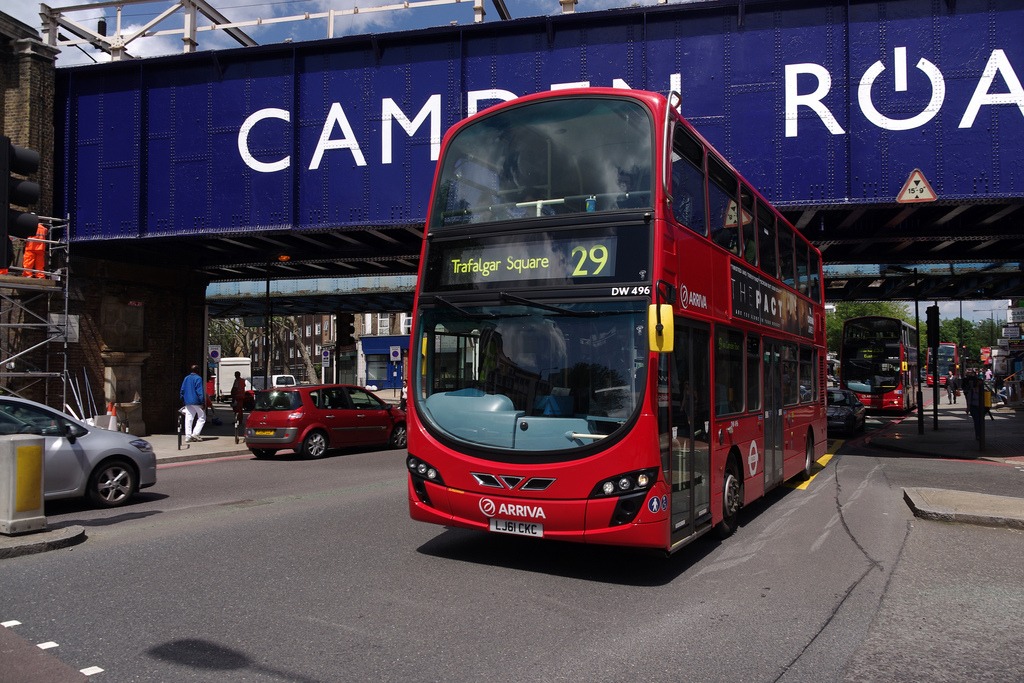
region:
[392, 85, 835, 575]
Red double decker bus.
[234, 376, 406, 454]
Small red car.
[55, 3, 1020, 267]
Large blue overpass with white letters.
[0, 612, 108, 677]
Small white squares painted on the road.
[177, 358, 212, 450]
Man wearing white pants.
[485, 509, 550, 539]
White license plate with black letters and numbers.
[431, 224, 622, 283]
Black informational sign with yellow letters and numbers.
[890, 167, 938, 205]
Red and white warning sign with black letters and symbols.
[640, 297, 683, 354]
Large yellow side mirror.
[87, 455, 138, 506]
Black tire with silver rim.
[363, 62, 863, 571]
a red double deck bus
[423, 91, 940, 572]
two red double deck buses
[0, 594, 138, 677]
lines in the street for crosswalk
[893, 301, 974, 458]
a stop light on a city corner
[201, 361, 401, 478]
a red compact car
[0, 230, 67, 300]
someone wearing orange pants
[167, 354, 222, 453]
a man wearing white pants and a blue shirt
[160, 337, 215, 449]
a man walking on sidewalk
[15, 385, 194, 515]
a small silver car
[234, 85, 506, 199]
a view of text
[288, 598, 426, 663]
a view of road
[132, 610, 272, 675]
a view of shadow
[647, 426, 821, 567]
a view of tire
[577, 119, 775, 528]
a view of door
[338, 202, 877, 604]
a view of bus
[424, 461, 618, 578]
a view of number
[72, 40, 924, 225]
a view of board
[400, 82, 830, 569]
red and black transportation bus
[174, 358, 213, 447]
man wearing a blue shirt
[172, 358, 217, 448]
man walking on the sidewalk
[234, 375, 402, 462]
red car on the road beside the curb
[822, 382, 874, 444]
car between two red buses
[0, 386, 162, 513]
silver car behind a red car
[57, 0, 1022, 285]
blue bridge above the bus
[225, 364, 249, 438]
man in red walking on the sidewalk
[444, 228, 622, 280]
sign in yellow letters on front of bus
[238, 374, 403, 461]
red car driving down the street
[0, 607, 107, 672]
white markings on the street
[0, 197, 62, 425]
person dressed in orange standing on a scaffold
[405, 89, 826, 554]
red double deck bus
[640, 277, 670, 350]
yellow rear view mirror on side of bus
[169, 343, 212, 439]
man wearing white pants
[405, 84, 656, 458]
front window of a bus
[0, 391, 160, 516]
silver car going down the street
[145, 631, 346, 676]
sign shadow on the street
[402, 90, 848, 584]
bus driving on road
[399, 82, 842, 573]
bus under bridge is red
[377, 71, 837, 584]
bus under bridge is double decker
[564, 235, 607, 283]
bus number on front of bus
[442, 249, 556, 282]
bus destination on front of bus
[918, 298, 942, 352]
traffic light under bridge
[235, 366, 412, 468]
small car by sidewalk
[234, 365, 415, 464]
small car is red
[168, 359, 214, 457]
man walking on sidewalk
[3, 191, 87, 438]
scaffolding in front of building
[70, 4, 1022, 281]
white words on blue overpass